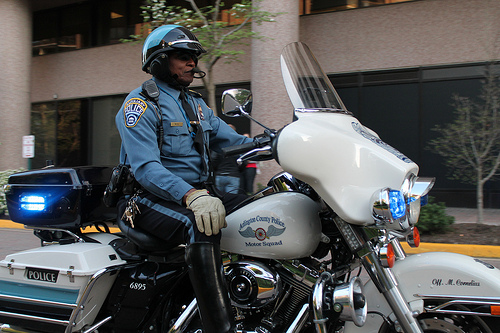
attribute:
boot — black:
[187, 240, 234, 330]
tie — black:
[170, 82, 211, 178]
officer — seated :
[123, 34, 318, 328]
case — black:
[7, 168, 109, 225]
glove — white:
[183, 186, 225, 237]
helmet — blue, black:
[131, 22, 212, 70]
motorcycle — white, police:
[114, 23, 272, 332]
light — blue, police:
[14, 189, 56, 214]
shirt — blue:
[114, 73, 283, 230]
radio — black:
[119, 73, 169, 109]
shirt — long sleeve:
[113, 79, 273, 203]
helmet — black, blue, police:
[142, 20, 205, 73]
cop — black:
[71, 17, 342, 331]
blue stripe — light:
[131, 191, 203, 244]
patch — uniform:
[121, 98, 149, 128]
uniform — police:
[110, 83, 277, 325]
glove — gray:
[182, 185, 230, 237]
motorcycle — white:
[17, 39, 497, 330]